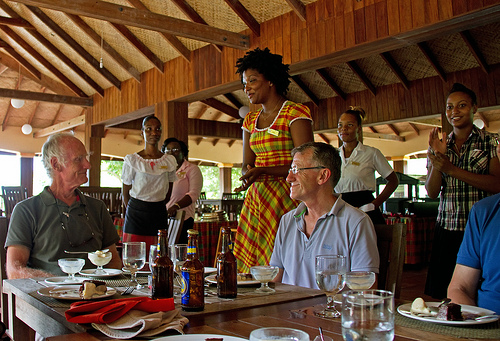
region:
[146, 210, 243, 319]
bottles on the table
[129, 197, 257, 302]
the bottles are brown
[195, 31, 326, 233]
the waitress is taking orders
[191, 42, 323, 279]
the waitress is wearing a colorful dress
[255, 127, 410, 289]
man on the right is wearing glasses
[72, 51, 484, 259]
people are standing in the background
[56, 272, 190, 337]
napkins are on the table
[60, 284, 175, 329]
the napkin is red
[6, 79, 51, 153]
the lights are off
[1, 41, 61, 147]
the lights are hanging from the ceiling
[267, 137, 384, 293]
guy wearing eye glasses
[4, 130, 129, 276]
guy wearing a cyan polo shirt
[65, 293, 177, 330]
red napkin on the table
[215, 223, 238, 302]
a glass bottle of beer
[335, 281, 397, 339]
glass of water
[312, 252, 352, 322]
a glass of water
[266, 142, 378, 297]
person wearing a light blue shirt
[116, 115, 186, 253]
woman wearing a white shirt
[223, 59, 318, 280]
woman wearing a colorful dress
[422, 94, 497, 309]
guy wearing a stripped shirt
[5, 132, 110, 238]
man sitting in a chair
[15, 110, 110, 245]
man wearing gray shirt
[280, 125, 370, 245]
man wearing a gray shirt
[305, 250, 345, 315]
glass on a table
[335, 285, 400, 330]
glass on a table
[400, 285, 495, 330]
plate on a table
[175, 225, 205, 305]
bottle on a table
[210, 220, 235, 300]
bottle on a table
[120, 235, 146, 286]
glass on a table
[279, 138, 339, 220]
the man is wearing glasses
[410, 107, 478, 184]
the woman is clapping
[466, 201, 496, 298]
the shirt is blue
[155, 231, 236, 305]
the beer bottles are brown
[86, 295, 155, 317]
the napkin is red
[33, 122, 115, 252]
the man is smiling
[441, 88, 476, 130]
the woman is smiling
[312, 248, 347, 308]
the glass is filled with water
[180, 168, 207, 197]
the sleeve is pink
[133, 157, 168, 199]
the blouse is white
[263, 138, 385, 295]
Man sitting at table in light blue shirt.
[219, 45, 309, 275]
Woman dressed in red, yellow and green plaid dress.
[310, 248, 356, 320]
Glass of water sitting on table.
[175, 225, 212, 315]
Bottle of beer sitting on table.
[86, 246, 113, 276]
Bowl of ice cream sitting in front of man.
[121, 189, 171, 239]
Woman wearing a black apron.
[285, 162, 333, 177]
Man wearing eyeglasses over eyes.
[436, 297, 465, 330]
Chocolate cake sitting on man's plate.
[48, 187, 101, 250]
Man wearing eyeglasses on chain around neck.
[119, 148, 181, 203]
Woman dressed in white peasant blouse.